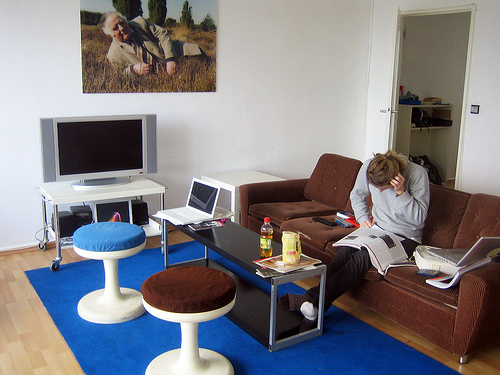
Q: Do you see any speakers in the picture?
A: Yes, there are speakers.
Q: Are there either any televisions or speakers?
A: Yes, there are speakers.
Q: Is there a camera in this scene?
A: No, there are no cameras.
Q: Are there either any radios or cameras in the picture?
A: No, there are no cameras or radios.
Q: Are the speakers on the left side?
A: Yes, the speakers are on the left of the image.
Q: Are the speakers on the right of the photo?
A: No, the speakers are on the left of the image.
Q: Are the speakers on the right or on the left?
A: The speakers are on the left of the image.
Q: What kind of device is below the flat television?
A: The devices are speakers.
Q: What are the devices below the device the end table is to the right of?
A: The devices are speakers.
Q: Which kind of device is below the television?
A: The devices are speakers.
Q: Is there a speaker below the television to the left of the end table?
A: Yes, there are speakers below the TV.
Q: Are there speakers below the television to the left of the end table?
A: Yes, there are speakers below the TV.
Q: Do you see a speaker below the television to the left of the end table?
A: Yes, there are speakers below the TV.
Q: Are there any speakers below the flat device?
A: Yes, there are speakers below the TV.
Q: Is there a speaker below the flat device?
A: Yes, there are speakers below the TV.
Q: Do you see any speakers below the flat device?
A: Yes, there are speakers below the TV.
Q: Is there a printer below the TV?
A: No, there are speakers below the TV.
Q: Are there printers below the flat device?
A: No, there are speakers below the TV.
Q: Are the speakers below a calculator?
A: No, the speakers are below a television.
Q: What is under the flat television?
A: The speakers are under the television.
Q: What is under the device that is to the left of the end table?
A: The speakers are under the television.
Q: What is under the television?
A: The speakers are under the television.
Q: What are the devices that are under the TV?
A: The devices are speakers.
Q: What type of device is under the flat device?
A: The devices are speakers.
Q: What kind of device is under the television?
A: The devices are speakers.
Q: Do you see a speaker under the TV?
A: Yes, there are speakers under the TV.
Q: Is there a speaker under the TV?
A: Yes, there are speakers under the TV.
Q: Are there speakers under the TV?
A: Yes, there are speakers under the TV.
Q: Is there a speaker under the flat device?
A: Yes, there are speakers under the TV.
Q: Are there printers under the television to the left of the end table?
A: No, there are speakers under the TV.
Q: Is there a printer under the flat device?
A: No, there are speakers under the TV.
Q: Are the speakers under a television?
A: Yes, the speakers are under a television.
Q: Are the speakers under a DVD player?
A: No, the speakers are under a television.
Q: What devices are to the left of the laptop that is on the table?
A: The devices are speakers.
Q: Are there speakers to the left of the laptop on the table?
A: Yes, there are speakers to the left of the laptop computer.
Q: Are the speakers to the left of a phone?
A: No, the speakers are to the left of a laptop.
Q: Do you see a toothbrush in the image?
A: No, there are no toothbrushes.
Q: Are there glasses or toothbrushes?
A: No, there are no toothbrushes or glasses.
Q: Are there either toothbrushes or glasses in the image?
A: No, there are no toothbrushes or glasses.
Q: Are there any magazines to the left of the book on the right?
A: Yes, there are magazines to the left of the book.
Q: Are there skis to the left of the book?
A: No, there are magazines to the left of the book.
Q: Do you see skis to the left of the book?
A: No, there are magazines to the left of the book.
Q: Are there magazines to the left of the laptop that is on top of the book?
A: Yes, there are magazines to the left of the laptop.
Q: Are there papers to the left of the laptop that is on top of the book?
A: No, there are magazines to the left of the laptop computer.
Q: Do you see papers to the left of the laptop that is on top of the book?
A: No, there are magazines to the left of the laptop computer.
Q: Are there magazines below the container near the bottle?
A: Yes, there are magazines below the container.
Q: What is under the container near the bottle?
A: The magazines are under the container.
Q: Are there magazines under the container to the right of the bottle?
A: Yes, there are magazines under the container.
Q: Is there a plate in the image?
A: No, there are no plates.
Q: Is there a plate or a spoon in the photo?
A: No, there are no plates or spoons.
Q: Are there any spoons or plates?
A: No, there are no plates or spoons.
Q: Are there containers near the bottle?
A: Yes, there is a container near the bottle.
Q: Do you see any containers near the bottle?
A: Yes, there is a container near the bottle.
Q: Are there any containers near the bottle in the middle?
A: Yes, there is a container near the bottle.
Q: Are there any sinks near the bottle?
A: No, there is a container near the bottle.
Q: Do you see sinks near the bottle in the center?
A: No, there is a container near the bottle.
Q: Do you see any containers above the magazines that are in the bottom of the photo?
A: Yes, there is a container above the magazines.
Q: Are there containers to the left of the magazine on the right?
A: Yes, there is a container to the left of the magazine.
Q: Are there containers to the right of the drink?
A: Yes, there is a container to the right of the drink.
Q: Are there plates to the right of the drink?
A: No, there is a container to the right of the drink.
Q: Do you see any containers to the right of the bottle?
A: Yes, there is a container to the right of the bottle.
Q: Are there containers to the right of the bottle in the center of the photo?
A: Yes, there is a container to the right of the bottle.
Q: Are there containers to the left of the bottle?
A: No, the container is to the right of the bottle.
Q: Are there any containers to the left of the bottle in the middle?
A: No, the container is to the right of the bottle.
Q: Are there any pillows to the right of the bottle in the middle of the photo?
A: No, there is a container to the right of the bottle.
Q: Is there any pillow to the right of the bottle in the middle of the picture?
A: No, there is a container to the right of the bottle.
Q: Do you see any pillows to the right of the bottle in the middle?
A: No, there is a container to the right of the bottle.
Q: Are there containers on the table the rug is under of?
A: Yes, there is a container on the table.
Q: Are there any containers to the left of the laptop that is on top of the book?
A: Yes, there is a container to the left of the laptop.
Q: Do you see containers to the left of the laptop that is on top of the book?
A: Yes, there is a container to the left of the laptop.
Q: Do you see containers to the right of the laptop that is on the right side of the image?
A: No, the container is to the left of the laptop.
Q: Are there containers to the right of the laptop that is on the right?
A: No, the container is to the left of the laptop.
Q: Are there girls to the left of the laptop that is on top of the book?
A: No, there is a container to the left of the laptop.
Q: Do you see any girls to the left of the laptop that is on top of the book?
A: No, there is a container to the left of the laptop.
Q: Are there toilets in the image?
A: No, there are no toilets.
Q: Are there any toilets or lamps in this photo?
A: No, there are no toilets or lamps.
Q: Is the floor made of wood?
A: Yes, the floor is made of wood.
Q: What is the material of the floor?
A: The floor is made of wood.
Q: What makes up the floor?
A: The floor is made of wood.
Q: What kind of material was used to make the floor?
A: The floor is made of wood.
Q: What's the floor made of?
A: The floor is made of wood.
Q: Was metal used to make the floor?
A: No, the floor is made of wood.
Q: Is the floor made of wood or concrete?
A: The floor is made of wood.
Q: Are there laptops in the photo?
A: Yes, there is a laptop.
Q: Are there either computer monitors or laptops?
A: Yes, there is a laptop.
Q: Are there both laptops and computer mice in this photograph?
A: No, there is a laptop but no computer mice.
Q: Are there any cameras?
A: No, there are no cameras.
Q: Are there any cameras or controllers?
A: No, there are no cameras or controllers.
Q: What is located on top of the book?
A: The laptop is on top of the book.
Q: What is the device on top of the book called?
A: The device is a laptop.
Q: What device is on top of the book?
A: The device is a laptop.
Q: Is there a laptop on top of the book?
A: Yes, there is a laptop on top of the book.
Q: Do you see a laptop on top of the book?
A: Yes, there is a laptop on top of the book.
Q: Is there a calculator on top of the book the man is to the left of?
A: No, there is a laptop on top of the book.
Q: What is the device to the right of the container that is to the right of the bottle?
A: The device is a laptop.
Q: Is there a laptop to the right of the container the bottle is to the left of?
A: Yes, there is a laptop to the right of the container.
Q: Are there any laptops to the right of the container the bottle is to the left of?
A: Yes, there is a laptop to the right of the container.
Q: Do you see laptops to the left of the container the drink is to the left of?
A: No, the laptop is to the right of the container.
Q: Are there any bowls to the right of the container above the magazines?
A: No, there is a laptop to the right of the container.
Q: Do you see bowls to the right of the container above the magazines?
A: No, there is a laptop to the right of the container.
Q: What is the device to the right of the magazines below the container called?
A: The device is a laptop.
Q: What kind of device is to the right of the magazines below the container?
A: The device is a laptop.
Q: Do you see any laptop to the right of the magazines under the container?
A: Yes, there is a laptop to the right of the magazines.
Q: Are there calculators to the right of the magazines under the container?
A: No, there is a laptop to the right of the magazines.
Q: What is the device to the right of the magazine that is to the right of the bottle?
A: The device is a laptop.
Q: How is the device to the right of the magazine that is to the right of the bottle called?
A: The device is a laptop.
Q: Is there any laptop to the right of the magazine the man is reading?
A: Yes, there is a laptop to the right of the magazine.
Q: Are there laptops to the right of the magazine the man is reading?
A: Yes, there is a laptop to the right of the magazine.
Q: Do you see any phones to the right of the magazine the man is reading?
A: No, there is a laptop to the right of the magazine.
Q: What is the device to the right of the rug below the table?
A: The device is a laptop.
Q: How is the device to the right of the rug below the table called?
A: The device is a laptop.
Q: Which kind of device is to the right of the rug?
A: The device is a laptop.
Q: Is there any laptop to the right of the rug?
A: Yes, there is a laptop to the right of the rug.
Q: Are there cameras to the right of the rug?
A: No, there is a laptop to the right of the rug.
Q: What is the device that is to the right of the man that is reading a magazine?
A: The device is a laptop.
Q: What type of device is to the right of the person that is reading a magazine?
A: The device is a laptop.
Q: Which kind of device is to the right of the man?
A: The device is a laptop.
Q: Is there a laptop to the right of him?
A: Yes, there is a laptop to the right of the man.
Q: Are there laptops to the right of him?
A: Yes, there is a laptop to the right of the man.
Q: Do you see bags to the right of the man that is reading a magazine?
A: No, there is a laptop to the right of the man.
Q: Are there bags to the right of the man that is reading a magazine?
A: No, there is a laptop to the right of the man.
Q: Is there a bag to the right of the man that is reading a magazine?
A: No, there is a laptop to the right of the man.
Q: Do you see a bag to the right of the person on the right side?
A: No, there is a laptop to the right of the man.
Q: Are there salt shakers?
A: No, there are no salt shakers.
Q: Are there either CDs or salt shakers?
A: No, there are no salt shakers or cds.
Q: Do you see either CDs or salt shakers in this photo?
A: No, there are no salt shakers or cds.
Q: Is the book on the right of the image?
A: Yes, the book is on the right of the image.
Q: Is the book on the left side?
A: No, the book is on the right of the image.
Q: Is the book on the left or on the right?
A: The book is on the right of the image.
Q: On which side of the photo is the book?
A: The book is on the right of the image.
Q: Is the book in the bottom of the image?
A: Yes, the book is in the bottom of the image.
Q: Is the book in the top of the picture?
A: No, the book is in the bottom of the image.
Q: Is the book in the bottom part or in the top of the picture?
A: The book is in the bottom of the image.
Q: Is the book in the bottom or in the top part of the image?
A: The book is in the bottom of the image.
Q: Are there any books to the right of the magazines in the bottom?
A: Yes, there is a book to the right of the magazines.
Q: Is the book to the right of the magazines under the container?
A: Yes, the book is to the right of the magazines.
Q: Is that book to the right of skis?
A: No, the book is to the right of the magazines.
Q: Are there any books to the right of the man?
A: Yes, there is a book to the right of the man.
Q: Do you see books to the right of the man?
A: Yes, there is a book to the right of the man.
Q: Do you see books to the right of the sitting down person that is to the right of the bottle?
A: Yes, there is a book to the right of the man.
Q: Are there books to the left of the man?
A: No, the book is to the right of the man.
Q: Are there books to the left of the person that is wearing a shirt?
A: No, the book is to the right of the man.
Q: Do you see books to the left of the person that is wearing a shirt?
A: No, the book is to the right of the man.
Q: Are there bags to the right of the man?
A: No, there is a book to the right of the man.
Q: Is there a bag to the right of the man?
A: No, there is a book to the right of the man.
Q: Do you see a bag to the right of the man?
A: No, there is a book to the right of the man.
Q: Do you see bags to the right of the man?
A: No, there is a book to the right of the man.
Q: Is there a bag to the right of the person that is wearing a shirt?
A: No, there is a book to the right of the man.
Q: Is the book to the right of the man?
A: Yes, the book is to the right of the man.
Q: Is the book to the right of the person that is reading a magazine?
A: Yes, the book is to the right of the man.